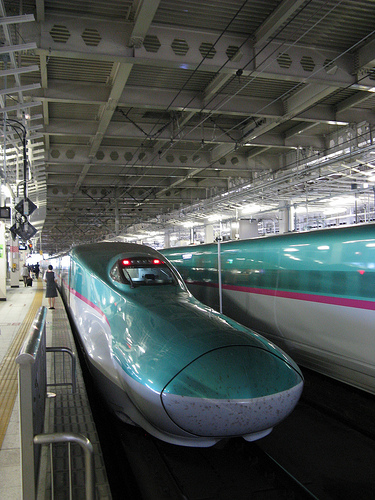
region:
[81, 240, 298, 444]
A train on the railway track.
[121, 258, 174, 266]
Headlights on the train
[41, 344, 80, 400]
Metal bars on the side walk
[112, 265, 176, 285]
Windscreen on the train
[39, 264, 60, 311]
A woman at the station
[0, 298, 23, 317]
A pavement with cabro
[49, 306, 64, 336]
A side walk at the station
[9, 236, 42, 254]
Traffic signal at the station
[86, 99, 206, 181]
Roofing at the station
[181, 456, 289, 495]
Railway track at the station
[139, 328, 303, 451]
the front of a green and white train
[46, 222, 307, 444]
a green and white train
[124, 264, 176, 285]
the front windshield of a train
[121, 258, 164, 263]
a pair of red lights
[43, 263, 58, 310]
a woman in a dress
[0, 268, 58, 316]
part of a train platform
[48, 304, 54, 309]
a pair of womans black shoes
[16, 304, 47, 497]
a silver hand railing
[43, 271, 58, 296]
a black womans dress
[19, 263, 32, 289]
someone rolling a piece of luggage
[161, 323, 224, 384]
aqua on the top of train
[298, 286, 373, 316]
purple stripe on the train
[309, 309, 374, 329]
grey under the purple stripe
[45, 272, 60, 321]
woman on the platform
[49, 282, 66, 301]
woman is wearing a dress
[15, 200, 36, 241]
signs in the train station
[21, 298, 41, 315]
yellow stripe next to platform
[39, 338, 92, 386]
railing on the platform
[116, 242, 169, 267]
red lights on the front of the train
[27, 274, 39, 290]
woman rolling luggage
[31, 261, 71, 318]
woman on train platform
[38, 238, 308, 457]
large train in station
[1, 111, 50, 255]
back side of train signs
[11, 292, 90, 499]
metal safety railing at train station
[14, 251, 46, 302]
several people on train platform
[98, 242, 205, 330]
red lights on train window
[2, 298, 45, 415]
Yellow safety ground bumps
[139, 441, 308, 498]
railroad train tracks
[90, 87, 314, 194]
electrical cables at train station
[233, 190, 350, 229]
lighting at train station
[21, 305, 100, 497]
Metal safety railing near train track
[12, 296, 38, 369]
Yellow safety line near train tracks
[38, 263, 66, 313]
Woman in a dark dress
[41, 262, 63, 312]
Woman standing next to train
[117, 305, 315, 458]
Front end of a high speed train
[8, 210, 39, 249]
Signs at a train station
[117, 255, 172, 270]
Two red lights on the front of a train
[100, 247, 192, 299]
Front windshield of a high speed train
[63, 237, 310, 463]
Green train stopped at train station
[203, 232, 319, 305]
Green train with a red stripe